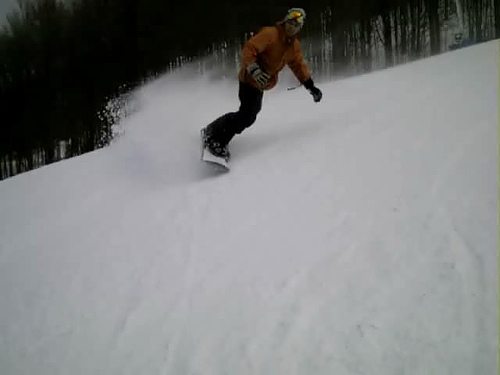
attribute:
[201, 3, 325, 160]
person — moving, snowboarding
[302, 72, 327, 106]
glove — black, brown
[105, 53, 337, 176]
snow — flying, in the air, white, splashing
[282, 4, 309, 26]
hat — brown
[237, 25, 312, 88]
jacket — orange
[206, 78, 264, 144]
pants — dark, black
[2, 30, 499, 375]
hill — large, snow covered, white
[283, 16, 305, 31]
goggles — yellow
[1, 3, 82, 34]
sky — darkening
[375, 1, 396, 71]
tree — dead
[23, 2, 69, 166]
tree — green